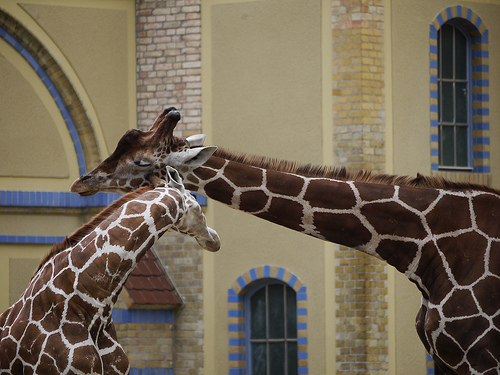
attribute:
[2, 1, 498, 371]
building — ornate, beige, blue, gray, off white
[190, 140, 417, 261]
neck — long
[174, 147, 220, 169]
ear — white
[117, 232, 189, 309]
shingles — red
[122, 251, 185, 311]
tile — red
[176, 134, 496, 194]
mane — soft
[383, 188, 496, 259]
spots — large, brown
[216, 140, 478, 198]
hair — brown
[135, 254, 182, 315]
shingles — red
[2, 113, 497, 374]
giraffes — yellow, brown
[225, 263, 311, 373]
frame — blu, yellow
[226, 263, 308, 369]
trim — blue, yellow, striped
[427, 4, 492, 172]
trim — striped, blue, yellow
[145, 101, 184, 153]
horns — short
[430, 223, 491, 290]
spot — brown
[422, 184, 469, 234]
spot — brown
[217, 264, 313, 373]
border — blue, gray, stone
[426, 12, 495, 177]
border — stone, blue, gray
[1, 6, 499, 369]
wall — yellow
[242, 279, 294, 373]
window — paned glass